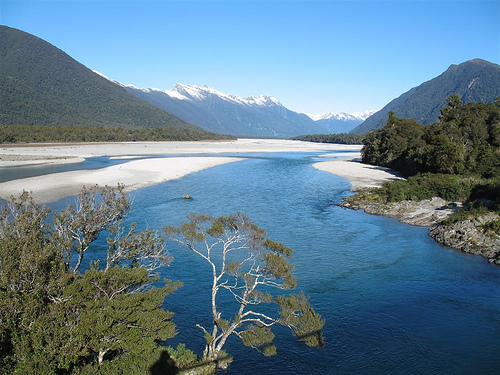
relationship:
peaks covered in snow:
[117, 73, 374, 131] [158, 80, 218, 105]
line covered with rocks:
[314, 145, 495, 268] [384, 214, 498, 261]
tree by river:
[430, 88, 471, 152] [49, 150, 495, 372]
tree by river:
[468, 103, 491, 173] [49, 150, 495, 372]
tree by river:
[486, 105, 498, 141] [6, 139, 489, 367]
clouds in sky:
[97, 22, 154, 62] [3, 5, 499, 137]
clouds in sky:
[0, 0, 499, 84] [0, 3, 499, 112]